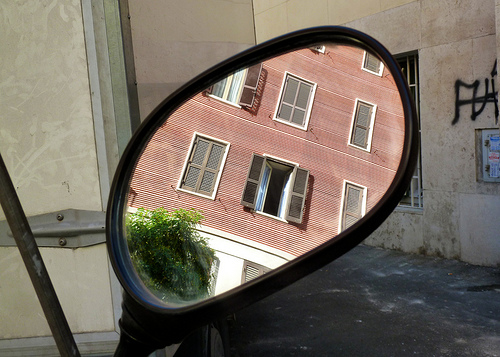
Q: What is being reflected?
A: Windows.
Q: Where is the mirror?
A: On the side of a car.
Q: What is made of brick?
A: Building.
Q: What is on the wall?
A: Graffiti.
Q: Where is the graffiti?
A: On the wall.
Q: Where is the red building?
A: In the mirror.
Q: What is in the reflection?
A: The building.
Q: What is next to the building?
A: The green tree.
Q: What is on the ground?
A: The asphalt road.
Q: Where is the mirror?
A: On the car.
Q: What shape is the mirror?
A: Oblong.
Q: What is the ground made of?
A: Pavement.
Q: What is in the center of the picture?
A: A side mirror.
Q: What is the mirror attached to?
A: A car.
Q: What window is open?
A: The one in the middle.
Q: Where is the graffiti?
A: On the back wall.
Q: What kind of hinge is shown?
A: A door hinge.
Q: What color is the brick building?
A: Red.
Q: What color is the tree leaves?
A: Green.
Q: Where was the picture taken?
A: From a vehicle.